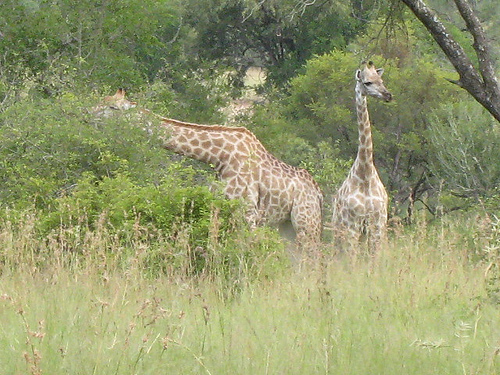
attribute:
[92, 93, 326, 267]
giraffe — eating, foraging, eating leaves, stretched out, tall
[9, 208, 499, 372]
grass — tall, grazing, green, gone to seed, brown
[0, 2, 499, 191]
background — woods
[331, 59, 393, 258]
giraffe — looking away, brown, white, tall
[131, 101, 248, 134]
mane — brown, short, bristly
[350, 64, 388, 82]
ears — white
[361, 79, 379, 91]
eyes — dark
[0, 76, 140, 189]
brush — eaten, green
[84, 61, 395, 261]
giraffes — grazing, 2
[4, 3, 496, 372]
field — grassy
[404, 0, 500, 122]
branches — of tree, tree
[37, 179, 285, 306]
bush — growing